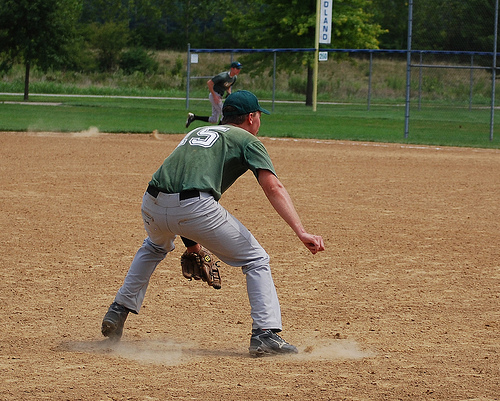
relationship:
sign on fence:
[317, 47, 327, 61] [185, 42, 499, 110]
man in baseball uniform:
[82, 81, 340, 367] [89, 83, 316, 359]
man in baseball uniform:
[82, 81, 340, 367] [117, 126, 279, 329]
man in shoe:
[82, 81, 340, 367] [244, 323, 299, 359]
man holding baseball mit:
[82, 81, 340, 367] [178, 249, 223, 291]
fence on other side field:
[178, 31, 499, 150] [0, 71, 485, 141]